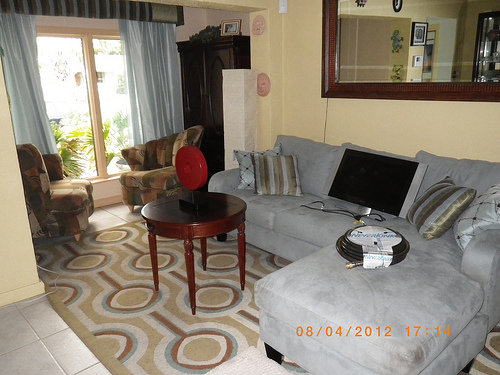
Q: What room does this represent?
A: It represents the living room.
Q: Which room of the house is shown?
A: It is a living room.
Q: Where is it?
A: This is at the living room.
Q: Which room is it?
A: It is a living room.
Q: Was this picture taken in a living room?
A: Yes, it was taken in a living room.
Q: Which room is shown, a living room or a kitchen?
A: It is a living room.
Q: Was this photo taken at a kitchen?
A: No, the picture was taken in a living room.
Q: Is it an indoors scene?
A: Yes, it is indoors.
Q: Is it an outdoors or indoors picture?
A: It is indoors.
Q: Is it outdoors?
A: No, it is indoors.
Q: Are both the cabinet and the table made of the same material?
A: Yes, both the cabinet and the table are made of wood.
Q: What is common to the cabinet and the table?
A: The material, both the cabinet and the table are wooden.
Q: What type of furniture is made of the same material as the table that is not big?
A: The cabinet is made of the same material as the table.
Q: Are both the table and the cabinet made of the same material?
A: Yes, both the table and the cabinet are made of wood.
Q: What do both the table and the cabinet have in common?
A: The material, both the table and the cabinet are wooden.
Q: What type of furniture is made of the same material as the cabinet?
A: The table is made of the same material as the cabinet.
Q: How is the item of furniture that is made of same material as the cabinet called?
A: The piece of furniture is a table.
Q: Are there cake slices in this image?
A: No, there are no cake slices.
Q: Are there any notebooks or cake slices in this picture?
A: No, there are no cake slices or notebooks.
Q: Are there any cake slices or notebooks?
A: No, there are no cake slices or notebooks.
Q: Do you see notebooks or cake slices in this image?
A: No, there are no cake slices or notebooks.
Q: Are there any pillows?
A: Yes, there is a pillow.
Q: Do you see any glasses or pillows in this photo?
A: Yes, there is a pillow.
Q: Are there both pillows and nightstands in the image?
A: No, there is a pillow but no nightstands.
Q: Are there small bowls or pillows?
A: Yes, there is a small pillow.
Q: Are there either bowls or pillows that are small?
A: Yes, the pillow is small.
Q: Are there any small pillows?
A: Yes, there is a small pillow.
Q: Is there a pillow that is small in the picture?
A: Yes, there is a small pillow.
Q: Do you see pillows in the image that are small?
A: Yes, there is a pillow that is small.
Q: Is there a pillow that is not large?
A: Yes, there is a small pillow.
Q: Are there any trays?
A: No, there are no trays.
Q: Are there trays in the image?
A: No, there are no trays.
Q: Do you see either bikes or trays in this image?
A: No, there are no trays or bikes.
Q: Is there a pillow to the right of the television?
A: Yes, there is a pillow to the right of the television.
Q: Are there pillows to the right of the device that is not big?
A: Yes, there is a pillow to the right of the television.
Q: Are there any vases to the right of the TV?
A: No, there is a pillow to the right of the TV.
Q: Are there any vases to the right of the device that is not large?
A: No, there is a pillow to the right of the TV.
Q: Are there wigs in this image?
A: No, there are no wigs.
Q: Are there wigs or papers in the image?
A: No, there are no wigs or papers.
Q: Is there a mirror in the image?
A: Yes, there is a mirror.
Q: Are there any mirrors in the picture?
A: Yes, there is a mirror.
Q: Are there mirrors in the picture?
A: Yes, there is a mirror.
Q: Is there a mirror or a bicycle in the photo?
A: Yes, there is a mirror.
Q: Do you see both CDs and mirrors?
A: No, there is a mirror but no cds.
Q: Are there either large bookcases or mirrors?
A: Yes, there is a large mirror.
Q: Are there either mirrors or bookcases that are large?
A: Yes, the mirror is large.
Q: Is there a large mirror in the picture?
A: Yes, there is a large mirror.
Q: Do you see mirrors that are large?
A: Yes, there is a mirror that is large.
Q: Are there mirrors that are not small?
A: Yes, there is a large mirror.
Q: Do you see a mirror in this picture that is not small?
A: Yes, there is a large mirror.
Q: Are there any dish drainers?
A: No, there are no dish drainers.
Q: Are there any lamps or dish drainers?
A: No, there are no dish drainers or lamps.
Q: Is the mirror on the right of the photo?
A: Yes, the mirror is on the right of the image.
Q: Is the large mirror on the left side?
A: No, the mirror is on the right of the image.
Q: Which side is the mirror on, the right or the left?
A: The mirror is on the right of the image.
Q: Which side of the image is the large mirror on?
A: The mirror is on the right of the image.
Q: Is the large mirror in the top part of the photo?
A: Yes, the mirror is in the top of the image.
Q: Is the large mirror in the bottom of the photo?
A: No, the mirror is in the top of the image.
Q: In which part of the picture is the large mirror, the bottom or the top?
A: The mirror is in the top of the image.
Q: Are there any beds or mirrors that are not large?
A: No, there is a mirror but it is large.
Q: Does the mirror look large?
A: Yes, the mirror is large.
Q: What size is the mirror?
A: The mirror is large.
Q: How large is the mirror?
A: The mirror is large.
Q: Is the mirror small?
A: No, the mirror is large.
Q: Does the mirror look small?
A: No, the mirror is large.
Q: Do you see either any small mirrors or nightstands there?
A: No, there is a mirror but it is large.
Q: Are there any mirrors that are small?
A: No, there is a mirror but it is large.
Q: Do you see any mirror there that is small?
A: No, there is a mirror but it is large.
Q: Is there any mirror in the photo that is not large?
A: No, there is a mirror but it is large.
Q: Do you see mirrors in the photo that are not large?
A: No, there is a mirror but it is large.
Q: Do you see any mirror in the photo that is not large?
A: No, there is a mirror but it is large.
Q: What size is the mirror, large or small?
A: The mirror is large.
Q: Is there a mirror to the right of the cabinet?
A: Yes, there is a mirror to the right of the cabinet.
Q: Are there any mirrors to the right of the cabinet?
A: Yes, there is a mirror to the right of the cabinet.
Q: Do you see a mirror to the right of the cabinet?
A: Yes, there is a mirror to the right of the cabinet.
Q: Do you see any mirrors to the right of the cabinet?
A: Yes, there is a mirror to the right of the cabinet.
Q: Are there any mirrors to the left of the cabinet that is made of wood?
A: No, the mirror is to the right of the cabinet.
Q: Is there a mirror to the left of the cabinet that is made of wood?
A: No, the mirror is to the right of the cabinet.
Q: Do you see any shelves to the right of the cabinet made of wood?
A: No, there is a mirror to the right of the cabinet.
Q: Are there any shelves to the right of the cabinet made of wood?
A: No, there is a mirror to the right of the cabinet.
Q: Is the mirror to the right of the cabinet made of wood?
A: Yes, the mirror is to the right of the cabinet.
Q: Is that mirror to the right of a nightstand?
A: No, the mirror is to the right of the cabinet.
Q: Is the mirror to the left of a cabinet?
A: No, the mirror is to the right of a cabinet.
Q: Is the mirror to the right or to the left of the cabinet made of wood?
A: The mirror is to the right of the cabinet.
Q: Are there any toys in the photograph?
A: No, there are no toys.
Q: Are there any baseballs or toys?
A: No, there are no toys or baseballs.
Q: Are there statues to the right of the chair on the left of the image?
A: Yes, there is a statue to the right of the chair.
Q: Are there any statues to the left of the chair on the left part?
A: No, the statue is to the right of the chair.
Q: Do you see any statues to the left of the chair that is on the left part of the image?
A: No, the statue is to the right of the chair.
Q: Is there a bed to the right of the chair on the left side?
A: No, there is a statue to the right of the chair.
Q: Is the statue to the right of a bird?
A: No, the statue is to the right of a chair.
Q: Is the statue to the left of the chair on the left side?
A: No, the statue is to the right of the chair.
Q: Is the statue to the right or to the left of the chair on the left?
A: The statue is to the right of the chair.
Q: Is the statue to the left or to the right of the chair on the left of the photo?
A: The statue is to the right of the chair.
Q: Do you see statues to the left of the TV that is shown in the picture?
A: Yes, there is a statue to the left of the TV.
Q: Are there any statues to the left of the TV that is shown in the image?
A: Yes, there is a statue to the left of the TV.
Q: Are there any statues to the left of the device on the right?
A: Yes, there is a statue to the left of the TV.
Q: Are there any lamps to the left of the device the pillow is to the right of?
A: No, there is a statue to the left of the television.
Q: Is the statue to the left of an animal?
A: No, the statue is to the left of a television.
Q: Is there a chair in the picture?
A: Yes, there is a chair.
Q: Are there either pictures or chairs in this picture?
A: Yes, there is a chair.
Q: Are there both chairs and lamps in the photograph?
A: No, there is a chair but no lamps.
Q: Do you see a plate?
A: No, there are no plates.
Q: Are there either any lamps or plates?
A: No, there are no plates or lamps.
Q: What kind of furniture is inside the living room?
A: The piece of furniture is a chair.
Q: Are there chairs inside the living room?
A: Yes, there is a chair inside the living room.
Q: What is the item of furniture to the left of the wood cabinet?
A: The piece of furniture is a chair.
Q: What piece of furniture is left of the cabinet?
A: The piece of furniture is a chair.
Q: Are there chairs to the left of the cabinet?
A: Yes, there is a chair to the left of the cabinet.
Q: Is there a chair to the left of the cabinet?
A: Yes, there is a chair to the left of the cabinet.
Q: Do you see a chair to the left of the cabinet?
A: Yes, there is a chair to the left of the cabinet.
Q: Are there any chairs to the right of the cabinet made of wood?
A: No, the chair is to the left of the cabinet.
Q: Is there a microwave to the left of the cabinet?
A: No, there is a chair to the left of the cabinet.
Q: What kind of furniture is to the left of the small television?
A: The piece of furniture is a chair.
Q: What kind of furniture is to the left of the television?
A: The piece of furniture is a chair.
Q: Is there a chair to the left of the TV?
A: Yes, there is a chair to the left of the TV.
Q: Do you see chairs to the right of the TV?
A: No, the chair is to the left of the TV.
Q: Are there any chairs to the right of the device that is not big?
A: No, the chair is to the left of the TV.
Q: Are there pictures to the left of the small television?
A: No, there is a chair to the left of the TV.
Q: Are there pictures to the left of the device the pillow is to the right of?
A: No, there is a chair to the left of the TV.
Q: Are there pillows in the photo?
A: Yes, there is a pillow.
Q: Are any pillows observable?
A: Yes, there is a pillow.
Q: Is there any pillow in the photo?
A: Yes, there is a pillow.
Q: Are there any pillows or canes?
A: Yes, there is a pillow.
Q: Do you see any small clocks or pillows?
A: Yes, there is a small pillow.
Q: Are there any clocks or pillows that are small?
A: Yes, the pillow is small.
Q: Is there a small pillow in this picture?
A: Yes, there is a small pillow.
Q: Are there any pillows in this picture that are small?
A: Yes, there is a pillow that is small.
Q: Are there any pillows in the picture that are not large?
A: Yes, there is a small pillow.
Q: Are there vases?
A: No, there are no vases.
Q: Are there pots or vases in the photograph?
A: No, there are no vases or pots.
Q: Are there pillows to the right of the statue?
A: Yes, there is a pillow to the right of the statue.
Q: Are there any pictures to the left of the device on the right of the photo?
A: No, there is a pillow to the left of the TV.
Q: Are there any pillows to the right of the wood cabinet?
A: Yes, there is a pillow to the right of the cabinet.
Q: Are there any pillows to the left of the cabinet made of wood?
A: No, the pillow is to the right of the cabinet.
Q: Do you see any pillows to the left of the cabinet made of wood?
A: No, the pillow is to the right of the cabinet.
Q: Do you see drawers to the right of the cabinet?
A: No, there is a pillow to the right of the cabinet.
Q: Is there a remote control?
A: No, there are no remote controls.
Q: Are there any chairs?
A: Yes, there is a chair.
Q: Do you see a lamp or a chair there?
A: Yes, there is a chair.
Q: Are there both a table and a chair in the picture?
A: Yes, there are both a chair and a table.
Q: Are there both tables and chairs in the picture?
A: Yes, there are both a chair and a table.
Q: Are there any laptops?
A: No, there are no laptops.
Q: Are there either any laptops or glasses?
A: No, there are no laptops or glasses.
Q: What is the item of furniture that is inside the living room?
A: The piece of furniture is a chair.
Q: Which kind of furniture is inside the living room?
A: The piece of furniture is a chair.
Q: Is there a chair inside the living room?
A: Yes, there is a chair inside the living room.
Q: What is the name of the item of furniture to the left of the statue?
A: The piece of furniture is a chair.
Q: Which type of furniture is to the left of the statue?
A: The piece of furniture is a chair.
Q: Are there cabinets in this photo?
A: Yes, there is a cabinet.